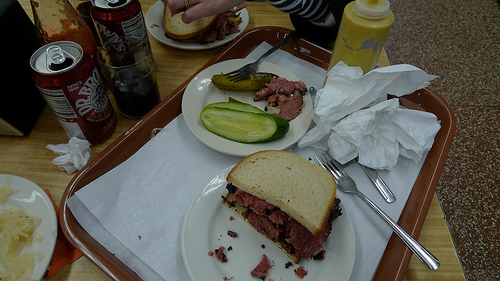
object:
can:
[79, 1, 153, 72]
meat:
[235, 185, 331, 258]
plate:
[180, 59, 312, 156]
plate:
[180, 167, 356, 281]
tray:
[59, 26, 453, 280]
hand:
[168, 0, 239, 23]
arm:
[263, 0, 329, 21]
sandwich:
[160, 0, 228, 44]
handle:
[356, 192, 440, 272]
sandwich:
[220, 148, 342, 263]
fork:
[313, 150, 442, 272]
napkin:
[296, 61, 443, 172]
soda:
[24, 36, 107, 152]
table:
[4, 2, 454, 278]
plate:
[0, 174, 61, 279]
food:
[4, 187, 45, 279]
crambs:
[208, 224, 278, 274]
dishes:
[201, 70, 342, 278]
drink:
[82, 0, 153, 66]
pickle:
[199, 97, 288, 144]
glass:
[104, 56, 165, 118]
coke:
[30, 39, 118, 149]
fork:
[218, 28, 299, 83]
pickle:
[212, 68, 271, 88]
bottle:
[32, 39, 118, 146]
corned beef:
[251, 74, 307, 100]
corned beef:
[267, 90, 305, 120]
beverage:
[112, 68, 159, 119]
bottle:
[326, 1, 395, 85]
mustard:
[322, 0, 395, 84]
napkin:
[43, 136, 92, 176]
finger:
[181, 0, 243, 23]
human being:
[161, 0, 346, 29]